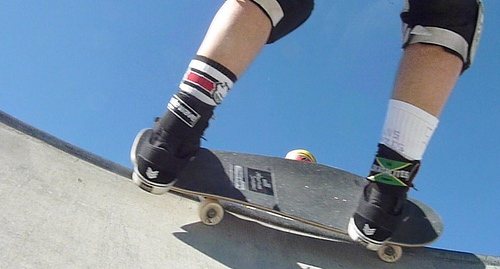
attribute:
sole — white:
[131, 127, 179, 194]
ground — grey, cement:
[417, 147, 457, 178]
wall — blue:
[0, 0, 500, 256]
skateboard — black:
[229, 171, 356, 204]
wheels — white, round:
[200, 202, 401, 267]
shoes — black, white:
[134, 124, 431, 258]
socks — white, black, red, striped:
[183, 53, 439, 157]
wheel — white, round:
[375, 238, 407, 263]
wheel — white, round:
[193, 197, 230, 226]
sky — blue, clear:
[1, 1, 498, 257]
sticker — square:
[225, 162, 276, 197]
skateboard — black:
[128, 126, 446, 247]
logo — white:
[357, 221, 380, 243]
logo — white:
[138, 162, 160, 179]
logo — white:
[209, 73, 227, 105]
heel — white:
[345, 220, 385, 250]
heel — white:
[128, 163, 170, 194]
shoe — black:
[344, 165, 413, 255]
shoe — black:
[134, 115, 192, 197]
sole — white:
[131, 127, 171, 194]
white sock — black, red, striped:
[375, 94, 442, 162]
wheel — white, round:
[186, 203, 248, 235]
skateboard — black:
[179, 141, 447, 243]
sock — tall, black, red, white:
[166, 54, 236, 136]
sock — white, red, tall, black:
[379, 98, 439, 163]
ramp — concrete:
[1, 114, 494, 267]